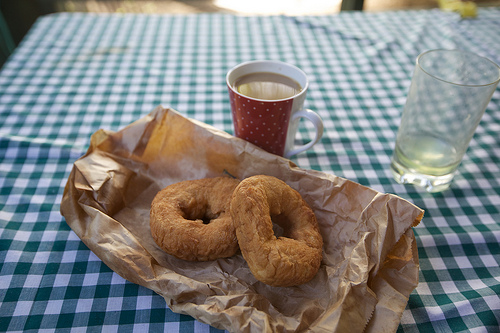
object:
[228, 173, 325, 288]
donut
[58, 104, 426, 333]
paper bag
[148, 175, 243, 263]
donut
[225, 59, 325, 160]
cup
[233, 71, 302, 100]
coffee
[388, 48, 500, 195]
drinking glass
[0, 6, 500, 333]
table cloth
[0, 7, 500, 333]
table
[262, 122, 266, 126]
polka dot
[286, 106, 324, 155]
handle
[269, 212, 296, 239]
hole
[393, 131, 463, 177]
liquid